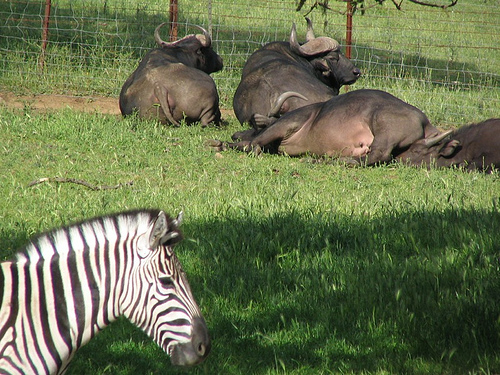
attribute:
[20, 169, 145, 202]
branch — dead , grey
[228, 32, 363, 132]
animal — horned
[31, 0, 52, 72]
post — red, metal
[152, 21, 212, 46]
horns — sharp, large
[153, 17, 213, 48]
horns — sharp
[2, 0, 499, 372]
greengrass — green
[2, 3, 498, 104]
fence — steel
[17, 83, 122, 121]
brown dirt — dirty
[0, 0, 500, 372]
grass — green, healthy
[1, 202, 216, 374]
zebra — black and white, large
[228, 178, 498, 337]
grass — tall